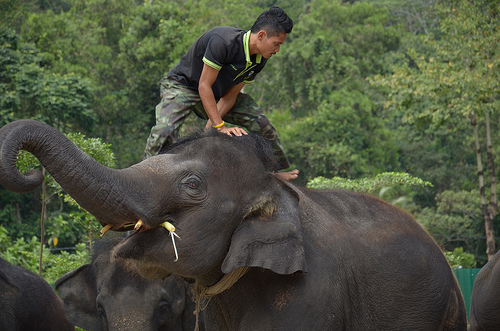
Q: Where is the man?
A: On the elephant.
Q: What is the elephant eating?
A: Bananas.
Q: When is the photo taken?
A: Daytime.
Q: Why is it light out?
A: It is daytime.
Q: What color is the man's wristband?
A: Yellow.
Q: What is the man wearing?
A: Pants and a shirt.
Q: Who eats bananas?
A: The elephant.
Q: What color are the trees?
A: Green.